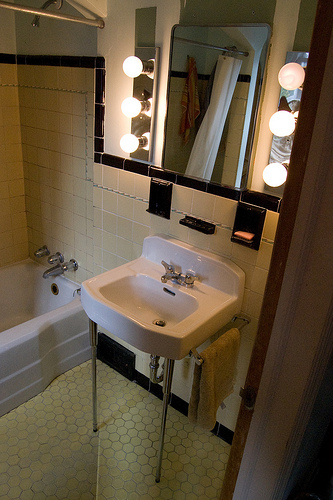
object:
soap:
[234, 230, 255, 241]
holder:
[231, 200, 268, 251]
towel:
[188, 326, 241, 430]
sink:
[80, 233, 246, 361]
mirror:
[161, 23, 272, 189]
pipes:
[149, 353, 165, 384]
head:
[32, 18, 41, 28]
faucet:
[43, 258, 79, 279]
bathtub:
[0, 255, 93, 417]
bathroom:
[3, 2, 330, 492]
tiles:
[122, 443, 134, 453]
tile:
[112, 440, 124, 452]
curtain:
[184, 53, 243, 181]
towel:
[176, 54, 200, 144]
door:
[218, 2, 332, 497]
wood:
[299, 126, 331, 243]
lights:
[122, 55, 144, 79]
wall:
[17, 12, 161, 284]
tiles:
[102, 187, 117, 215]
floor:
[43, 433, 85, 475]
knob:
[120, 133, 140, 154]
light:
[121, 98, 142, 118]